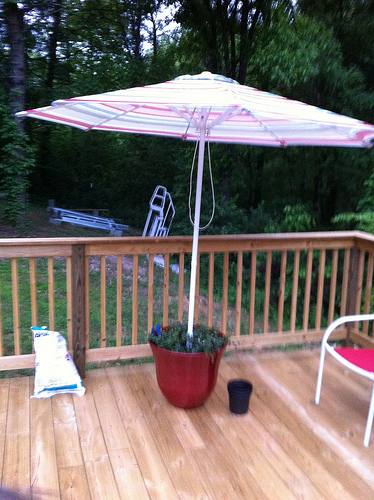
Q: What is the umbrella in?
A: A planter.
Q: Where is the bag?
A: On the deck.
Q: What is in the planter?
A: A plant.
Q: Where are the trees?
A: In the yard.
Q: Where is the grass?
A: On the slope.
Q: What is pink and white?
A: The chair.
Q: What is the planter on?
A: The patio.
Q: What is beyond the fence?
A: Woods.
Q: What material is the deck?
A: Wood.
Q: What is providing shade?
A: An umbrella.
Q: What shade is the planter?
A: Red.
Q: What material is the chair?
A: Metal.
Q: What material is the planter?
A: Ceramic.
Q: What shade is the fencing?
A: Brown.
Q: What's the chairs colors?
A: Red and white.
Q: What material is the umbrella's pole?
A: Metal.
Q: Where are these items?
A: Deck.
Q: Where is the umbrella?
A: Stuck in planter.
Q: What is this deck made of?
A: Wood.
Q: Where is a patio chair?
A: Right side of umbrella.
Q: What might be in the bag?
A: Potting soil.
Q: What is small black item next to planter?
A: Plant pot.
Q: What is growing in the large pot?
A: Plant with purple flowers.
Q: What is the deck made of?
A: Wood.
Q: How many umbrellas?
A: One.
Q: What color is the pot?
A: Maroon.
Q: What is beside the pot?
A: A small black pot.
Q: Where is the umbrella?
A: Inside the plant.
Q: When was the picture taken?
A: Dusk.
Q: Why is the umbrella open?
A: To give the plant shade.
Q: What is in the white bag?
A: Soil.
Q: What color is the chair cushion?
A: Pink.